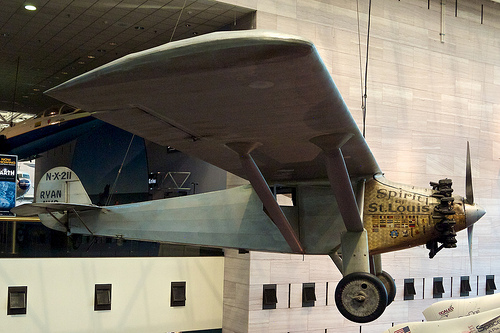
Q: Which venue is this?
A: This is a museum.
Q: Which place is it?
A: It is a museum.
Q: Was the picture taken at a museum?
A: Yes, it was taken in a museum.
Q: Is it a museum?
A: Yes, it is a museum.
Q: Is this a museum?
A: Yes, it is a museum.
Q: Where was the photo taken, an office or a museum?
A: It was taken at a museum.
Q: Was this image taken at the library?
A: No, the picture was taken in the museum.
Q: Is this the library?
A: No, it is the museum.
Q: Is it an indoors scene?
A: Yes, it is indoors.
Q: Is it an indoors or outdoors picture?
A: It is indoors.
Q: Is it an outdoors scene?
A: No, it is indoors.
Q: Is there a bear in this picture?
A: No, there are no bears.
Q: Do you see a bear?
A: No, there are no bears.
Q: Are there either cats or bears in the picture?
A: No, there are no bears or cats.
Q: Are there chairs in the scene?
A: No, there are no chairs.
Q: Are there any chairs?
A: No, there are no chairs.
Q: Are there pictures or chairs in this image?
A: No, there are no chairs or pictures.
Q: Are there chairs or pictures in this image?
A: No, there are no chairs or pictures.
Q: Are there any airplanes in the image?
A: Yes, there is an airplane.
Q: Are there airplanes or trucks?
A: Yes, there is an airplane.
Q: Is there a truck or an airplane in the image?
A: Yes, there is an airplane.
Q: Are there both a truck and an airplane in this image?
A: No, there is an airplane but no trucks.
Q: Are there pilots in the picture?
A: No, there are no pilots.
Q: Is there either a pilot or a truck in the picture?
A: No, there are no pilots or trucks.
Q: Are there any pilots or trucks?
A: No, there are no pilots or trucks.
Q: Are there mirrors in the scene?
A: No, there are no mirrors.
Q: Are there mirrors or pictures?
A: No, there are no mirrors or pictures.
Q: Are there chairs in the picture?
A: No, there are no chairs.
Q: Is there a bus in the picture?
A: No, there are no buses.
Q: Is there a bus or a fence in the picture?
A: No, there are no buses or fences.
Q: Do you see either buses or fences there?
A: No, there are no buses or fences.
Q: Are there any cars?
A: No, there are no cars.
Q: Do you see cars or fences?
A: No, there are no cars or fences.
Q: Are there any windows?
A: Yes, there are windows.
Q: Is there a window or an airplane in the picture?
A: Yes, there are windows.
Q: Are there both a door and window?
A: No, there are windows but no doors.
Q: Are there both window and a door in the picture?
A: No, there are windows but no doors.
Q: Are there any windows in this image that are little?
A: Yes, there are little windows.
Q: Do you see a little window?
A: Yes, there are little windows.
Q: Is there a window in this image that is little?
A: Yes, there are windows that are little.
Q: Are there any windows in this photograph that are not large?
A: Yes, there are little windows.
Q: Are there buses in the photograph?
A: No, there are no buses.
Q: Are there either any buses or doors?
A: No, there are no buses or doors.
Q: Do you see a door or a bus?
A: No, there are no buses or doors.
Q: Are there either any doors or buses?
A: No, there are no buses or doors.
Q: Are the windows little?
A: Yes, the windows are little.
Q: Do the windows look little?
A: Yes, the windows are little.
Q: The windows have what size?
A: The windows are little.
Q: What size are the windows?
A: The windows are little.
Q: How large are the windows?
A: The windows are little.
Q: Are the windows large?
A: No, the windows are little.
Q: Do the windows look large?
A: No, the windows are little.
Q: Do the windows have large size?
A: No, the windows are little.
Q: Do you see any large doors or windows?
A: No, there are windows but they are little.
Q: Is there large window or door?
A: No, there are windows but they are little.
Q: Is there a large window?
A: No, there are windows but they are little.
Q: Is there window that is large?
A: No, there are windows but they are little.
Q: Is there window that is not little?
A: No, there are windows but they are little.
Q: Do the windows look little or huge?
A: The windows are little.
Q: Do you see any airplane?
A: Yes, there is an airplane.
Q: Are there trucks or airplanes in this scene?
A: Yes, there is an airplane.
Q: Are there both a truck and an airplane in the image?
A: No, there is an airplane but no trucks.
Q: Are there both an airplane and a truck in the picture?
A: No, there is an airplane but no trucks.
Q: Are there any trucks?
A: No, there are no trucks.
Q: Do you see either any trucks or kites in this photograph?
A: No, there are no trucks or kites.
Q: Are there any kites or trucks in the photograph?
A: No, there are no trucks or kites.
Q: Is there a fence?
A: No, there are no fences.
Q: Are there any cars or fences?
A: No, there are no fences or cars.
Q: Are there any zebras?
A: No, there are no zebras.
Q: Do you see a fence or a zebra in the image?
A: No, there are no zebras or fences.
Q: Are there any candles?
A: No, there are no candles.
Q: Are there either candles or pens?
A: No, there are no candles or pens.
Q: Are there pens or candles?
A: No, there are no candles or pens.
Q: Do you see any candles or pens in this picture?
A: No, there are no candles or pens.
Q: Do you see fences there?
A: No, there are no fences.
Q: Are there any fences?
A: No, there are no fences.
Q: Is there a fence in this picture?
A: No, there are no fences.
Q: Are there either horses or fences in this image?
A: No, there are no fences or horses.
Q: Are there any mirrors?
A: No, there are no mirrors.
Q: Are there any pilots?
A: No, there are no pilots.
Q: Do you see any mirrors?
A: No, there are no mirrors.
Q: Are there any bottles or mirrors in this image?
A: No, there are no mirrors or bottles.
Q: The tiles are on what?
A: The tiles are on the wall.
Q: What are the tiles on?
A: The tiles are on the wall.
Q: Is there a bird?
A: No, there are no birds.